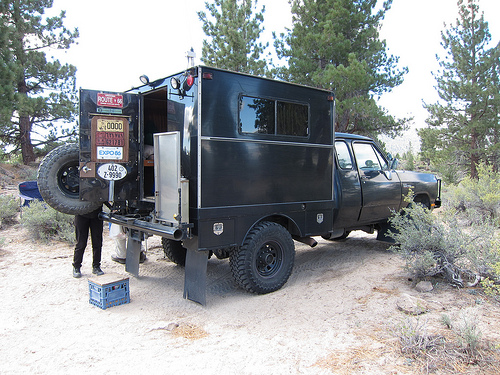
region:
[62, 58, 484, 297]
the truck in the woods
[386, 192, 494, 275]
the bush beside the truck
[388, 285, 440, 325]
the stone beside the bush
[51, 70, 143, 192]
the door is opoen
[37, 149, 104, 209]
the spare tire on the door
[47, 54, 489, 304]
the truck is black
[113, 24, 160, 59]
the clear blue sky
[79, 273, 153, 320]
the crate beside the door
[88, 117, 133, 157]
the license plates on the door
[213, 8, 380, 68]
trees with green leaves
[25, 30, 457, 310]
A truck sitting on a road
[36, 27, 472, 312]
A truck is parked on a road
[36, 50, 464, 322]
A truck with the back door open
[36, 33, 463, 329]
A truck that is being unloaded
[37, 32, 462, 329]
Someone is loading a truck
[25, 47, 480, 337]
A truck is carrying merchandise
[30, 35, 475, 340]
A truck has broken down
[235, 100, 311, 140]
A window on a truck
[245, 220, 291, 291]
A wheel and tire on a truck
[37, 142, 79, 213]
The spare tire of a truck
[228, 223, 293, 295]
black back wheel of truck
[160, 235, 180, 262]
black back wheel of truck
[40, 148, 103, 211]
spare wheel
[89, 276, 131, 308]
blue crate behind truck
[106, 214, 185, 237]
black pipe on truck rear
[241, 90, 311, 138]
window on truck rear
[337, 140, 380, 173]
wide windows on truck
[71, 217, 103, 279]
legs behind spare wheel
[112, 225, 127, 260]
legs behind mud flap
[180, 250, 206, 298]
mudflap of truck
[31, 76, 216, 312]
a crate behind the truck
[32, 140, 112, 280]
a person's legs under the tire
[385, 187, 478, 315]
a big rock by the bush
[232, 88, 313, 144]
a window on the side of the box truck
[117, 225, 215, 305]
black mud flaps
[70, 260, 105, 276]
the shoes are black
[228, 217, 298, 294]
the tire is black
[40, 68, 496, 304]
a bush beside the truck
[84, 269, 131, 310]
the crate is blue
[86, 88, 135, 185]
license plates on the inner door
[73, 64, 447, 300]
black truck in the wilderness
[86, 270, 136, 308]
plastic crate on the ground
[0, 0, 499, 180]
tall trees behind the truck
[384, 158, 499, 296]
shrubbery next to the truck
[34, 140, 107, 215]
spare tire hanging off the door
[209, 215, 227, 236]
logo mark on the side of the truck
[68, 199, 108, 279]
person wearing black pants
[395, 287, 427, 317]
rock next to the shrubbery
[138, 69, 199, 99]
lights hanging off the back of the truck